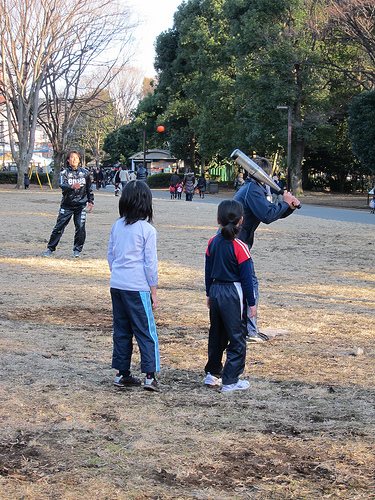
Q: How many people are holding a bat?
A: One.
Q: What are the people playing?
A: Baseball.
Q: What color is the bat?
A: Silver.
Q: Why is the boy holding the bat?
A: To hit the ball.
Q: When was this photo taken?
A: In the daytime.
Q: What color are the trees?
A: Green.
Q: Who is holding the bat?
A: A boy.